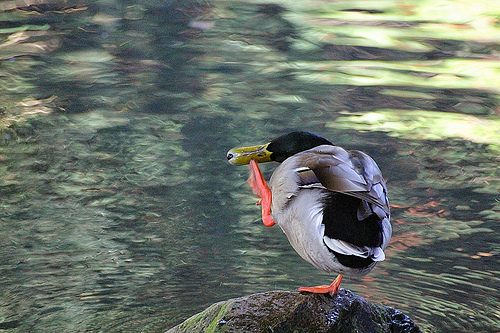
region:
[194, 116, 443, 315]
bird with orange feet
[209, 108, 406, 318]
Bird with yellow beak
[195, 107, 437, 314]
Bird with orange feet and yellow beak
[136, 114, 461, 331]
bird standing on a rock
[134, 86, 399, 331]
bird on a rock near the water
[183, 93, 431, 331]
duck with orange feet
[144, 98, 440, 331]
Duck with yellow beak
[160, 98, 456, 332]
Duck colored grey and black with white breast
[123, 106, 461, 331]
duck standing on a rock near some water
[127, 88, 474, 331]
duck with orange feet standing on a rock near some water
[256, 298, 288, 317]
part of a stone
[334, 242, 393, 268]
part of a tail wing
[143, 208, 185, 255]
part of a water body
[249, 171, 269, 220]
part of a leg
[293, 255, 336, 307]
part of a leg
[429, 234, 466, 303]
part of some waves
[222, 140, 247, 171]
part of a beak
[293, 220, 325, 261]
part of a feather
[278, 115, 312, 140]
head of a bird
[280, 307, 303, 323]
part of a stone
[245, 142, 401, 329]
the bird is on the rock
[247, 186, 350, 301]
the feet are orange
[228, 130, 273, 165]
the beek is green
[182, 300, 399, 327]
the stone is wet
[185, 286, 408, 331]
there is mould on the stone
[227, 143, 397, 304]
the bird is scratching its beck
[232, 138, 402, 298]
the bird is standing on one leg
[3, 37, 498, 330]
the photo was taken during the day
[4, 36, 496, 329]
the photo is blurry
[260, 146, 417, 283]
the feathers are black and grey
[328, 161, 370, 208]
part of a feather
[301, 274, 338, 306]
leg of a bird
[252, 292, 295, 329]
part of a rock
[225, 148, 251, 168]
beak of a bird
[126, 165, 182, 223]
part of a water body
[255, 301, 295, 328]
surface of a stone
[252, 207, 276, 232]
knee of a bird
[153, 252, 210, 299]
part of some waves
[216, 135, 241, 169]
tip of a beak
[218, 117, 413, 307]
a small mallard duck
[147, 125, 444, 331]
a duck on a rock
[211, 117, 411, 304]
a duck cleaning itself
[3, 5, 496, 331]
a duck stands near water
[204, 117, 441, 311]
a duck cleans its bill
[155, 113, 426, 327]
a duck with bright orange feet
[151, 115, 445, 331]
a duck stands on one foot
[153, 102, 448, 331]
a duck balances on a rock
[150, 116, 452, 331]
a duck preparing to go into water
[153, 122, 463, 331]
a mallard duck caring for itself